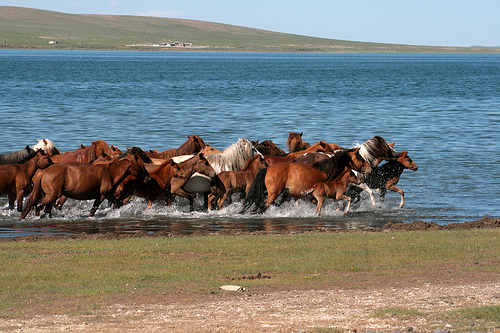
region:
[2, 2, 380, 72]
a building is on the side of the lake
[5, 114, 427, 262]
horses are running in the water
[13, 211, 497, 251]
seaweed is piled up by the water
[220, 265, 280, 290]
horse dung is on the grass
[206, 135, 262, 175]
a horse has a white mane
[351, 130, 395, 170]
a horse has a black and white mane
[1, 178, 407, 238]
the herd is kicking up water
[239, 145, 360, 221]
the mane and tail of the horse is black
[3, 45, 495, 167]
the water is blue with ripples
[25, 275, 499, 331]
a pathway is on the land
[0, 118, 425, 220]
wild horses on the beach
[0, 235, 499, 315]
thin patchy grass along the water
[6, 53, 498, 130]
ripples on blue water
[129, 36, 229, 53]
a clearing with building across the water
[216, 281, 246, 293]
a flat sun bleached rock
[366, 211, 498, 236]
piles of mud along the water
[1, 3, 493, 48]
a hill with no trees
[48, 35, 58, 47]
a distant building stands alone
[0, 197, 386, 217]
water splashing from horses running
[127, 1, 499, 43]
sky is clear and blue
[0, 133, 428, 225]
Group of horses running through the water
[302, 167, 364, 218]
Young brown foal in the water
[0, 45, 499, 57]
Shoreline across the water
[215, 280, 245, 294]
White rock partially buried in the sand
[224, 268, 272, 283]
Patch of dug up brown dirt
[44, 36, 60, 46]
White building on the green hillside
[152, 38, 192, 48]
Brown and white complex of buildings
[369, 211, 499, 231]
Dark brown dirt on the edge of the shore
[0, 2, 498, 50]
Green and brown hill on the other side of the water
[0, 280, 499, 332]
White patch of dirt on the shore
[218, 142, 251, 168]
white mane on horse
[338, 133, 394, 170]
horse's head is brown and mane white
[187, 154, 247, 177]
white horse in the pack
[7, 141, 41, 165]
horse has dark head and mane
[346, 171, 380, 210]
horse has white leg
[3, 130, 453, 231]
horses running through water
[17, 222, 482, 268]
grass along the water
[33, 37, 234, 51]
buildings on the other side of the water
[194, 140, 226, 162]
horse's head is tan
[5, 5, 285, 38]
hills behind the buildings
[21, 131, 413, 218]
a bunch of running horses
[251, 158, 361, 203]
a fully grown adult brown horse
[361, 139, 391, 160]
a fully grown adult white horse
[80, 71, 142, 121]
a bunch of ripples in the water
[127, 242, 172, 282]
a small patch of green grass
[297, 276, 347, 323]
a small patch of dirt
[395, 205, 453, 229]
a small heap of mud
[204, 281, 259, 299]
a small stone in the ground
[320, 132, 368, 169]
the head of a horse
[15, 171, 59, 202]
the tail of a horse